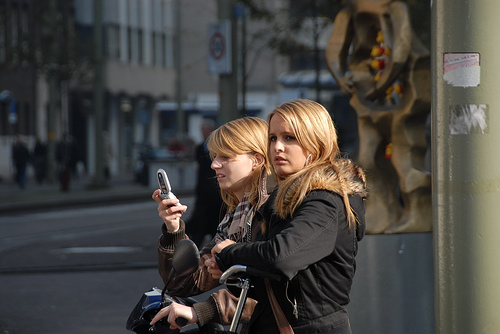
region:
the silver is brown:
[276, 107, 346, 189]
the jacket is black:
[289, 202, 341, 274]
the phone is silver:
[152, 167, 194, 214]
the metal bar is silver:
[208, 269, 245, 324]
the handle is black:
[240, 265, 285, 282]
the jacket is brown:
[212, 291, 244, 318]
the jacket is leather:
[211, 294, 237, 314]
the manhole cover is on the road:
[63, 236, 145, 263]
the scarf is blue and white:
[223, 204, 258, 230]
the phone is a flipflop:
[154, 167, 201, 213]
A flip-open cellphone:
[153, 152, 179, 196]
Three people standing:
[8, 132, 83, 190]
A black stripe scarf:
[212, 200, 258, 237]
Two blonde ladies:
[198, 106, 361, 198]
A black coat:
[268, 201, 373, 313]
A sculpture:
[339, 3, 431, 230]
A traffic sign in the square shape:
[191, 16, 256, 76]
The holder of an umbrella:
[216, 265, 252, 328]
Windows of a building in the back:
[110, 5, 170, 96]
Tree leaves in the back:
[249, 1, 331, 41]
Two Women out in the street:
[123, 91, 409, 332]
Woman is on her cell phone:
[136, 110, 271, 332]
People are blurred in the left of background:
[3, 106, 108, 209]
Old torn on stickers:
[434, 38, 496, 156]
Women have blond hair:
[146, 91, 388, 331]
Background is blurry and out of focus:
[1, 0, 359, 191]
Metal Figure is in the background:
[320, 0, 439, 238]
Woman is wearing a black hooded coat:
[216, 84, 382, 332]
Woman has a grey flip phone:
[138, 159, 193, 241]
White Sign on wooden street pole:
[201, 16, 240, 85]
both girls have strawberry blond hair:
[201, 91, 360, 228]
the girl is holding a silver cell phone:
[154, 162, 185, 216]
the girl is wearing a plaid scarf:
[204, 186, 266, 246]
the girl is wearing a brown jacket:
[148, 219, 258, 332]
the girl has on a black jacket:
[208, 182, 367, 332]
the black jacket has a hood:
[278, 158, 372, 250]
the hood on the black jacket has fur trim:
[273, 150, 371, 212]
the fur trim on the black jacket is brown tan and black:
[276, 153, 370, 211]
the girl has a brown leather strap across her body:
[250, 200, 297, 331]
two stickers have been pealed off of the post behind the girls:
[440, 48, 491, 149]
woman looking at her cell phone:
[153, 107, 271, 332]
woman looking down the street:
[206, 91, 370, 332]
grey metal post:
[429, 0, 499, 330]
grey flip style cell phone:
[156, 165, 182, 213]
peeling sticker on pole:
[437, 45, 490, 135]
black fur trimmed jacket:
[217, 159, 369, 331]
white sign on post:
[205, 20, 234, 71]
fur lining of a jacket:
[269, 155, 370, 216]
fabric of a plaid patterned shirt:
[214, 187, 269, 240]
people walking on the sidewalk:
[3, 126, 81, 193]